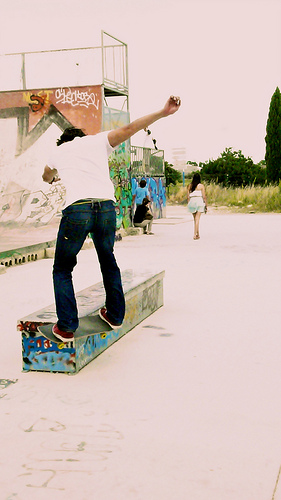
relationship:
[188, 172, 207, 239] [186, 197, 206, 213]
person wearing skirt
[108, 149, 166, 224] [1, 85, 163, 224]
grafitti on wall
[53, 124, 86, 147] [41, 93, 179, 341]
hair of person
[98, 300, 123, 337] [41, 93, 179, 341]
foot of person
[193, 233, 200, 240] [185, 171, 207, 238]
feet of person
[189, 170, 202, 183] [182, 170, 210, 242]
head of person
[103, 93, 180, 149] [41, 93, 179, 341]
arm of person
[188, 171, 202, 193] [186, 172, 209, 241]
hair of person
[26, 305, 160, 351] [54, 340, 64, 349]
skateboard has wheel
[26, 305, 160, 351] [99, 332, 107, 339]
skateboard has wheel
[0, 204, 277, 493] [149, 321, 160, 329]
ground has stain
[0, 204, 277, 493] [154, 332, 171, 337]
ground has stain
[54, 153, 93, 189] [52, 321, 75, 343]
person has foot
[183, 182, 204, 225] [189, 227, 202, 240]
person has feet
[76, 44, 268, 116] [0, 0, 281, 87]
sky has sky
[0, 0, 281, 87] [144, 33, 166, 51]
sky has white cloud